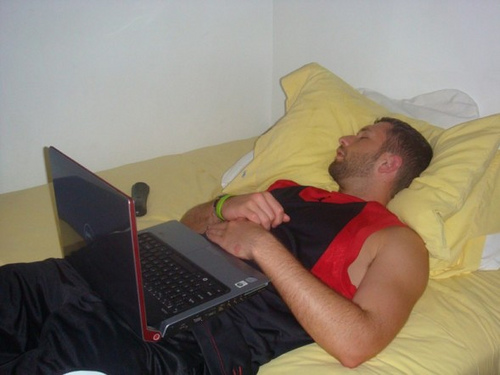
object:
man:
[0, 115, 433, 374]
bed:
[0, 135, 499, 374]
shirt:
[184, 178, 410, 374]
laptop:
[47, 145, 272, 343]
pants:
[0, 256, 210, 374]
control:
[131, 181, 150, 217]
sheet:
[0, 137, 499, 373]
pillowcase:
[220, 60, 500, 280]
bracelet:
[215, 193, 238, 221]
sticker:
[234, 280, 249, 289]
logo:
[82, 223, 95, 243]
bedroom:
[1, 3, 500, 374]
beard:
[327, 144, 385, 180]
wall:
[1, 2, 274, 194]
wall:
[276, 0, 498, 122]